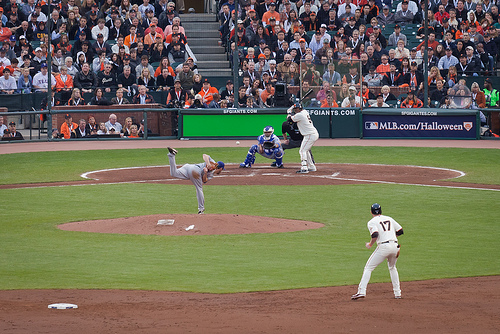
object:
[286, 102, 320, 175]
batter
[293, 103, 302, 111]
helmet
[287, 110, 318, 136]
shirt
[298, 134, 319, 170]
pants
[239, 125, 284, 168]
catcher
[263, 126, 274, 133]
helmet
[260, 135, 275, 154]
chest guard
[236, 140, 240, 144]
baseball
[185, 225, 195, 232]
rosin bag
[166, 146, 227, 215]
pitcher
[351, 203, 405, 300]
player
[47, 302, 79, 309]
second base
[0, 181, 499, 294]
infield grass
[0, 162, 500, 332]
infield dirt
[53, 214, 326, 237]
pitching mound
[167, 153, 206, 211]
pants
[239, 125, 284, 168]
equipment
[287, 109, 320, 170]
uniform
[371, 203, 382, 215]
helmet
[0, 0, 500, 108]
crowd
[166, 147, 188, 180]
leg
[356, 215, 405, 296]
uniform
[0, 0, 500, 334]
stadium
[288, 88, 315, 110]
bat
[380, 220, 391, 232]
number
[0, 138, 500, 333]
field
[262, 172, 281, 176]
home plate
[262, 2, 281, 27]
person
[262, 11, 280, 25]
shirt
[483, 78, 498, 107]
person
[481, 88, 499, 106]
shirt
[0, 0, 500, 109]
bleachers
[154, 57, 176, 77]
person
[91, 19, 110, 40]
person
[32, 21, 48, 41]
person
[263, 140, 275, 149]
catcher's mitt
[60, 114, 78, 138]
man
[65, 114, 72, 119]
cap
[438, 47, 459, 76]
man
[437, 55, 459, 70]
shirt